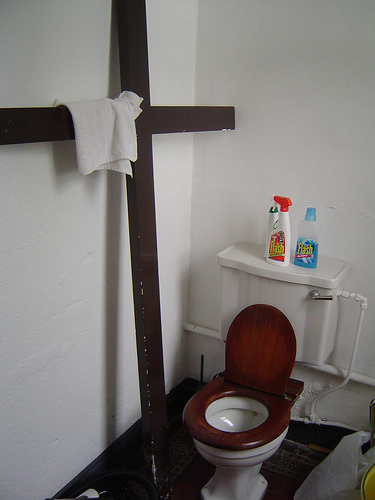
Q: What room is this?
A: The inside of a restroom.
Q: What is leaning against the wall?
A: A wood cross.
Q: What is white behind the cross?
A: The wall.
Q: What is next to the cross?
A: A white toilet.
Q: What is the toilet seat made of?
A: Wood.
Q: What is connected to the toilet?
A: A white pipe.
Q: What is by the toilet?
A: A cross.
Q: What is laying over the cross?
A: A white towel.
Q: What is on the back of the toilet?
A: Cleaners.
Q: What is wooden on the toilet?
A: The toilet seat.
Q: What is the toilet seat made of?
A: Wood.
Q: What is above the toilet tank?
A: Cleaning products.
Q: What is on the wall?
A: A wooden cross.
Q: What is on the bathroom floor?
A: Tiles.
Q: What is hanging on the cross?
A: A towel.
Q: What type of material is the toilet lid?
A: Wood.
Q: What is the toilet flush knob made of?
A: Metal.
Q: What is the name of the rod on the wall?
A: A pipe.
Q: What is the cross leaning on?
A: The wall.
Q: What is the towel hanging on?
A: A cross.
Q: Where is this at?
A: Bathroom.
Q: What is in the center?
A: Toilet.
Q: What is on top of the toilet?
A: Cleaning bottles.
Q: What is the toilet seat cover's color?
A: Brown.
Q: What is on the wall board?
A: Towel.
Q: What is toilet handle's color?
A: Silver.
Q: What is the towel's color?
A: White.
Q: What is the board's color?
A: Brown.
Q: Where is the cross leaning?
A: The wall.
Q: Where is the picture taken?
A: Bathroom.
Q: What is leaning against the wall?
A: Cross.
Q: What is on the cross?
A: Towel.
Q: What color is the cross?
A: Brown.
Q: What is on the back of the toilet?
A: Cleaner.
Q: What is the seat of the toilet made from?
A: Wood.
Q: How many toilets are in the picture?
A: One.